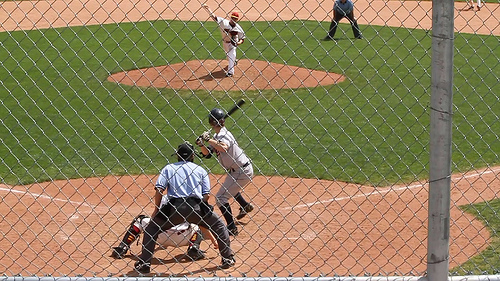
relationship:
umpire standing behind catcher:
[133, 140, 240, 275] [109, 192, 211, 264]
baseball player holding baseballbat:
[194, 108, 254, 236] [197, 96, 246, 146]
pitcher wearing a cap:
[197, 2, 246, 80] [228, 10, 239, 22]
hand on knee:
[348, 15, 359, 30] [350, 20, 361, 32]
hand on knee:
[327, 13, 339, 23] [326, 21, 341, 28]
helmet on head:
[206, 107, 227, 122] [207, 107, 226, 129]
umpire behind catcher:
[133, 140, 240, 275] [111, 191, 205, 259]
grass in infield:
[1, 17, 498, 187] [2, 2, 499, 222]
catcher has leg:
[109, 192, 211, 264] [190, 221, 200, 261]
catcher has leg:
[109, 192, 211, 264] [121, 212, 150, 249]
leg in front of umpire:
[190, 221, 200, 261] [156, 145, 236, 264]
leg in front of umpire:
[121, 212, 150, 249] [156, 145, 236, 264]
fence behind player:
[0, 2, 499, 280] [199, 12, 245, 75]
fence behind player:
[0, 2, 499, 280] [321, 0, 361, 42]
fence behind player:
[0, 2, 499, 280] [197, 99, 257, 235]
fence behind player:
[0, 2, 499, 280] [135, 140, 235, 276]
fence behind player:
[0, 2, 499, 280] [112, 190, 221, 259]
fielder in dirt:
[464, 2, 485, 19] [1, 3, 498, 37]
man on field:
[465, 0, 479, 11] [3, 0, 497, 279]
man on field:
[318, 0, 365, 40] [3, 0, 497, 279]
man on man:
[203, 2, 248, 70] [129, 138, 238, 272]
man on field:
[193, 103, 259, 231] [3, 0, 497, 279]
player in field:
[174, 107, 338, 231] [3, 0, 497, 279]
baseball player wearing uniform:
[194, 108, 254, 236] [206, 127, 256, 233]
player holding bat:
[174, 107, 338, 231] [202, 90, 290, 130]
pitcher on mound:
[197, 2, 246, 80] [99, 45, 355, 92]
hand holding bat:
[195, 127, 211, 140] [194, 92, 249, 140]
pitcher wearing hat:
[197, 2, 246, 80] [229, 13, 241, 19]